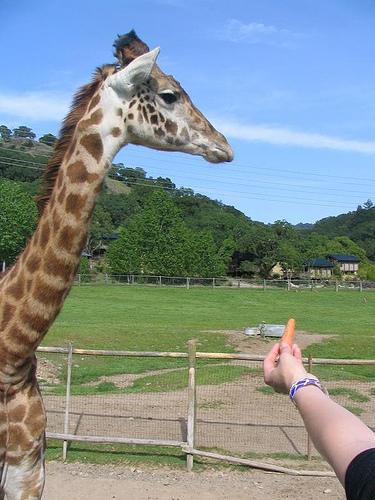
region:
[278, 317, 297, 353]
small piece of carrot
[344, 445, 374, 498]
sleeve of a black shirt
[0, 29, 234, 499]
the front part of a giraffe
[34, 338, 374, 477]
wooden post fence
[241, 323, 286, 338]
metal water trough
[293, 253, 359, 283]
two story house with a grey roof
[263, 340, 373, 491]
persons arm and hand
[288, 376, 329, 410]
purple and white giraffe patterned paper bracelet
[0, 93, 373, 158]
straight line of clouds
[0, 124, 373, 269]
tree covered hills in the background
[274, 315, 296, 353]
Orange carrot in the hand.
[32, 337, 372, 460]
Fence in the forefront.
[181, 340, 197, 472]
Wood post on the fence.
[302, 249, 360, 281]
Buildings in the background.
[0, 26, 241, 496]
Giraffe in the forefront.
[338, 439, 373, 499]
Black shirt on person.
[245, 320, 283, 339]
Metal container in the background.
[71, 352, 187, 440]
Black wire in the fence.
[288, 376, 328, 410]
Blue and white bracelet on the arm.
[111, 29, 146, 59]
Black tops on the horns.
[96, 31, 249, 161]
head of the giraffe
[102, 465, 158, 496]
dirt on the ground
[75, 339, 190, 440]
fence next to giraffe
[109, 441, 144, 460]
shadow on the ground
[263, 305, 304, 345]
carrot in person's hand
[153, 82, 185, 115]
eye of the giraffe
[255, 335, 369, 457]
arm of a person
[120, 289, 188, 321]
grass in the distance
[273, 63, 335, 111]
sky above the trees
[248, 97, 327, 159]
white cloud in the sky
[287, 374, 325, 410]
Blue and white bracelet on the wrist.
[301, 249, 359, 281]
House in the background.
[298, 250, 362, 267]
Black roof on the house.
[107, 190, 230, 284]
Tree in the background.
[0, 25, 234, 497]
Giraffe in the front.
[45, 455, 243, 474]
Small rocks in front of the fence.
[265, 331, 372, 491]
a person has their arm stretched out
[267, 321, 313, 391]
the person is holding a carrot in their hand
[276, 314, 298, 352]
the carrot is orange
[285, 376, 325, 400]
a wrist band on the person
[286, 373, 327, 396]
the wrist band is blue and white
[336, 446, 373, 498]
a black shirt being worn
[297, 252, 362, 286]
buildings around the area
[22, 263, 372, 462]
fence set up around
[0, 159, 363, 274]
a whole bunch of trees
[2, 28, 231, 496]
a giraffe beside the person